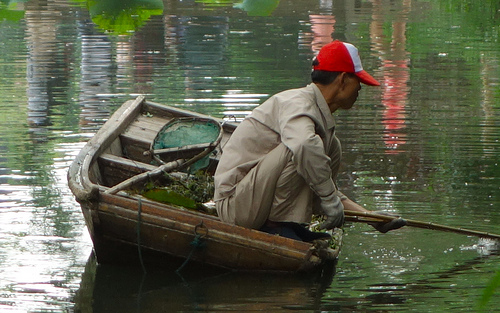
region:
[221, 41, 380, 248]
An Asian man fishing with a net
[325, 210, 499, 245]
A net the man is holding out into the water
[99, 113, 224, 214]
A blue spare net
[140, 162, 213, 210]
Various plants in the man's boat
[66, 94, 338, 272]
A small brown boat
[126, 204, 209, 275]
A blue rope to secure the boat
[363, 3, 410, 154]
The reflection of someone in red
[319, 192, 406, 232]
Dirty white gloves worn by the man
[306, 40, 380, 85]
The man's red and white baseball cap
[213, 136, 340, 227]
The man's khaki pants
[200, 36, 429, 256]
man on a boat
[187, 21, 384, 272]
grey suit on man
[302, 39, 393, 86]
red and white hat of man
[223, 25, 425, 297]
man wearing gloves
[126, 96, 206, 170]
green net om npat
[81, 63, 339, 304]
brown boat in water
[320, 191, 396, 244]
dirty gloves worn by man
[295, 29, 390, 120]
man has dark hair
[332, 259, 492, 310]
shadow on water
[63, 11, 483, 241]
reflections on water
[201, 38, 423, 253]
This is a man wearing a cap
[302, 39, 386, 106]
The cap is red and white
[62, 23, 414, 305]
There is a man sitting in a boat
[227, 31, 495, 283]
The man is fishing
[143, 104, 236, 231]
There is a fishing net in the boat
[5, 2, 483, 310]
The water is calm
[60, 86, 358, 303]
The boat is wooden and brown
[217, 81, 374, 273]
The man is wearing tan clothing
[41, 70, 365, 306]
The boat is leaning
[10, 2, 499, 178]
There are reflections on the water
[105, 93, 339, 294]
a ragged fishing boat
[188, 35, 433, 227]
a fisherman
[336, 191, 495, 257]
a fishing net dunked in water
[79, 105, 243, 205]
a fishing net out of water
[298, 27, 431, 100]
a red and white baseball cap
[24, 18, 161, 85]
reflections of people in the water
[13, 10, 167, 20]
reflections of plants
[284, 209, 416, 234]
a pair of grey work gloves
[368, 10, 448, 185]
a reflection of a woman walking by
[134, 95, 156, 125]
a leaf in a boat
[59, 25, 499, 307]
Man fishing in boat.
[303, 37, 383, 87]
Red and white hat on man's head.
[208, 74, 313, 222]
Grey Grey shirt and pants worn by man.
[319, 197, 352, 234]
White/grey glove worn by man.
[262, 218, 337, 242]
Blue shoes worn by man.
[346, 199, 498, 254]
Wooden fishing road.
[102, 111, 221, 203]
Wooden stick in green net.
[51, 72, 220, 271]
Brown and wooden boat.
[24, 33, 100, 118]
Pond water reflecting light.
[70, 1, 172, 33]
Moist green leaf.